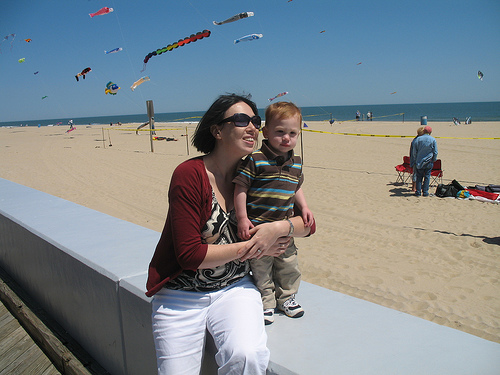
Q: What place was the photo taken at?
A: It was taken at the beach.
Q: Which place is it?
A: It is a beach.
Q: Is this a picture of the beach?
A: Yes, it is showing the beach.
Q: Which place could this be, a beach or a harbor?
A: It is a beach.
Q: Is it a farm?
A: No, it is a beach.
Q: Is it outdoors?
A: Yes, it is outdoors.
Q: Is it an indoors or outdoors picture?
A: It is outdoors.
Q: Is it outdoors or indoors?
A: It is outdoors.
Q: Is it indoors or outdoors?
A: It is outdoors.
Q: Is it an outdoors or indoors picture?
A: It is outdoors.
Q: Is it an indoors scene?
A: No, it is outdoors.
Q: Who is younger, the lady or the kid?
A: The kid is younger than the lady.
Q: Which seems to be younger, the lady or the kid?
A: The kid is younger than the lady.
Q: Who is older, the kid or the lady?
A: The lady is older than the kid.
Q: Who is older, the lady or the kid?
A: The lady is older than the kid.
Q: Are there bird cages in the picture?
A: No, there are no bird cages.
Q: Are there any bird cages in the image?
A: No, there are no bird cages.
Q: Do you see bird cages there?
A: No, there are no bird cages.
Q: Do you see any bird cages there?
A: No, there are no bird cages.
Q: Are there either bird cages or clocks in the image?
A: No, there are no bird cages or clocks.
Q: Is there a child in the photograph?
A: Yes, there is a child.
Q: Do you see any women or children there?
A: Yes, there is a child.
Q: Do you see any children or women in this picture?
A: Yes, there is a child.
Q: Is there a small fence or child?
A: Yes, there is a small child.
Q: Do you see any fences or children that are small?
A: Yes, the child is small.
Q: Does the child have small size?
A: Yes, the child is small.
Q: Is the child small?
A: Yes, the child is small.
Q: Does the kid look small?
A: Yes, the kid is small.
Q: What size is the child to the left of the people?
A: The child is small.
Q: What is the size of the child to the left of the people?
A: The child is small.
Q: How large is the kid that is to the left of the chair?
A: The child is small.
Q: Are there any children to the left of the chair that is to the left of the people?
A: Yes, there is a child to the left of the chair.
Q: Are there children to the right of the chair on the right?
A: No, the child is to the left of the chair.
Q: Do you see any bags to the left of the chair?
A: No, there is a child to the left of the chair.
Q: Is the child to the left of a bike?
A: No, the child is to the left of the chair.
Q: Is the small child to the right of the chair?
A: No, the kid is to the left of the chair.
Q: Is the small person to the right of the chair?
A: No, the kid is to the left of the chair.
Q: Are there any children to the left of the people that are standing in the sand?
A: Yes, there is a child to the left of the people.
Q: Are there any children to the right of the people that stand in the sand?
A: No, the child is to the left of the people.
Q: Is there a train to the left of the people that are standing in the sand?
A: No, there is a child to the left of the people.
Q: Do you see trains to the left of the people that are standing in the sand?
A: No, there is a child to the left of the people.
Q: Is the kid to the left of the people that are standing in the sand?
A: Yes, the kid is to the left of the people.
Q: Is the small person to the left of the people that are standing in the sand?
A: Yes, the kid is to the left of the people.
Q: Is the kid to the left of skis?
A: No, the kid is to the left of the people.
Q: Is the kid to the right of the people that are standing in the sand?
A: No, the kid is to the left of the people.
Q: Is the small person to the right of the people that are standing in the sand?
A: No, the kid is to the left of the people.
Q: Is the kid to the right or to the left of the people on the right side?
A: The kid is to the left of the people.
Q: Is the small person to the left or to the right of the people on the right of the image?
A: The kid is to the left of the people.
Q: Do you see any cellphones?
A: No, there are no cellphones.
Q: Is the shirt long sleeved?
A: Yes, the shirt is long sleeved.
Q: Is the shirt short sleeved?
A: No, the shirt is long sleeved.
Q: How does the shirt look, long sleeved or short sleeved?
A: The shirt is long sleeved.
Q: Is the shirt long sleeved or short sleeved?
A: The shirt is long sleeved.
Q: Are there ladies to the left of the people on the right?
A: Yes, there is a lady to the left of the people.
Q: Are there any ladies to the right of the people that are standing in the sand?
A: No, the lady is to the left of the people.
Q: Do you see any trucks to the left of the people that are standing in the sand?
A: No, there is a lady to the left of the people.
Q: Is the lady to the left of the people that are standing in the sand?
A: Yes, the lady is to the left of the people.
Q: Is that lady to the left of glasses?
A: No, the lady is to the left of the people.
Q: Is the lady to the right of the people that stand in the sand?
A: No, the lady is to the left of the people.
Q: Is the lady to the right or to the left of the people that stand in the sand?
A: The lady is to the left of the people.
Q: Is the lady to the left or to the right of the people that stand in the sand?
A: The lady is to the left of the people.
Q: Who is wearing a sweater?
A: The lady is wearing a sweater.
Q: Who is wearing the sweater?
A: The lady is wearing a sweater.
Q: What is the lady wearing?
A: The lady is wearing a sweater.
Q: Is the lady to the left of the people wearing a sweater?
A: Yes, the lady is wearing a sweater.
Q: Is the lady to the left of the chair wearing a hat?
A: No, the lady is wearing a sweater.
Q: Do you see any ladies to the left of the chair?
A: Yes, there is a lady to the left of the chair.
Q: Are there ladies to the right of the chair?
A: No, the lady is to the left of the chair.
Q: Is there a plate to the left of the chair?
A: No, there is a lady to the left of the chair.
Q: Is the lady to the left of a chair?
A: Yes, the lady is to the left of a chair.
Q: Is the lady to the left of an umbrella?
A: No, the lady is to the left of a chair.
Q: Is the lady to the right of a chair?
A: No, the lady is to the left of a chair.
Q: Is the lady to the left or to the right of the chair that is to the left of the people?
A: The lady is to the left of the chair.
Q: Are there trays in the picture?
A: No, there are no trays.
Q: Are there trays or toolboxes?
A: No, there are no trays or toolboxes.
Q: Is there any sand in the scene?
A: Yes, there is sand.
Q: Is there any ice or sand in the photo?
A: Yes, there is sand.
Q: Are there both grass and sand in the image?
A: No, there is sand but no grass.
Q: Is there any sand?
A: Yes, there is sand.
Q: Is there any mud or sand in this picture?
A: Yes, there is sand.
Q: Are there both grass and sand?
A: No, there is sand but no grass.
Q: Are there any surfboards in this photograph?
A: No, there are no surfboards.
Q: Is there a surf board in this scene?
A: No, there are no surfboards.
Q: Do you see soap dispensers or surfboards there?
A: No, there are no surfboards or soap dispensers.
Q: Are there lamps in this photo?
A: No, there are no lamps.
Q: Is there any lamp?
A: No, there are no lamps.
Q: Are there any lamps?
A: No, there are no lamps.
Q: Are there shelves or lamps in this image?
A: No, there are no lamps or shelves.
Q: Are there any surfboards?
A: No, there are no surfboards.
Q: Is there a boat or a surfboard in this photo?
A: No, there are no surfboards or boats.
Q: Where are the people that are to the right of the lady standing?
A: The people are standing in the sand.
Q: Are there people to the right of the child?
A: Yes, there are people to the right of the child.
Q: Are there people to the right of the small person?
A: Yes, there are people to the right of the child.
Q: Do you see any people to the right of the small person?
A: Yes, there are people to the right of the child.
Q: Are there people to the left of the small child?
A: No, the people are to the right of the child.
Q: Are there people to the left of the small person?
A: No, the people are to the right of the child.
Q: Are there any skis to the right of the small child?
A: No, there are people to the right of the kid.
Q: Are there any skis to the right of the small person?
A: No, there are people to the right of the kid.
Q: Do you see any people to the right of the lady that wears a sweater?
A: Yes, there are people to the right of the lady.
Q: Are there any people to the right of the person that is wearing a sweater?
A: Yes, there are people to the right of the lady.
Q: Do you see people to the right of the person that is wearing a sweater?
A: Yes, there are people to the right of the lady.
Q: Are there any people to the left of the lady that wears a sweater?
A: No, the people are to the right of the lady.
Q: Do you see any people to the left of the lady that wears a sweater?
A: No, the people are to the right of the lady.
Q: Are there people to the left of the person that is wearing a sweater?
A: No, the people are to the right of the lady.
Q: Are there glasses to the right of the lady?
A: No, there are people to the right of the lady.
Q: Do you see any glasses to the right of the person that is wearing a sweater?
A: No, there are people to the right of the lady.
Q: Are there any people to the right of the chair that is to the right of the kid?
A: Yes, there are people to the right of the chair.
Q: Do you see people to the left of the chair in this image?
A: No, the people are to the right of the chair.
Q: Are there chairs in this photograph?
A: Yes, there is a chair.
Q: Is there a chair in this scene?
A: Yes, there is a chair.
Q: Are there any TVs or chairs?
A: Yes, there is a chair.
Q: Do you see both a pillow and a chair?
A: No, there is a chair but no pillows.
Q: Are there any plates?
A: No, there are no plates.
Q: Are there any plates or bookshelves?
A: No, there are no plates or bookshelves.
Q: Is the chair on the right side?
A: Yes, the chair is on the right of the image.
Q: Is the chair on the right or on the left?
A: The chair is on the right of the image.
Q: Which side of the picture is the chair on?
A: The chair is on the right of the image.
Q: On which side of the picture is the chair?
A: The chair is on the right of the image.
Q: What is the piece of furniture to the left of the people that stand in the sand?
A: The piece of furniture is a chair.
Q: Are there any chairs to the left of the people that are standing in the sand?
A: Yes, there is a chair to the left of the people.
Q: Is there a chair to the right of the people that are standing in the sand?
A: No, the chair is to the left of the people.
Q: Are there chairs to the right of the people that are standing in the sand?
A: No, the chair is to the left of the people.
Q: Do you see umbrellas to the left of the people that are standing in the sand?
A: No, there is a chair to the left of the people.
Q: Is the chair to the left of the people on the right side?
A: Yes, the chair is to the left of the people.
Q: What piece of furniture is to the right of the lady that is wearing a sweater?
A: The piece of furniture is a chair.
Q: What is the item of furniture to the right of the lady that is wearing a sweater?
A: The piece of furniture is a chair.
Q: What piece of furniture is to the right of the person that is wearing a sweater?
A: The piece of furniture is a chair.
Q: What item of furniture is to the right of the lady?
A: The piece of furniture is a chair.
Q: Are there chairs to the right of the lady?
A: Yes, there is a chair to the right of the lady.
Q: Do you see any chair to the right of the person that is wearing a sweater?
A: Yes, there is a chair to the right of the lady.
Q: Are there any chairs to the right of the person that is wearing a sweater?
A: Yes, there is a chair to the right of the lady.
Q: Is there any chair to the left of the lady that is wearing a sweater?
A: No, the chair is to the right of the lady.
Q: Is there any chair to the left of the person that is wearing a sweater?
A: No, the chair is to the right of the lady.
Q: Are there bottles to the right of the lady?
A: No, there is a chair to the right of the lady.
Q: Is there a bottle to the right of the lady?
A: No, there is a chair to the right of the lady.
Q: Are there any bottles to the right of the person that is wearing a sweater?
A: No, there is a chair to the right of the lady.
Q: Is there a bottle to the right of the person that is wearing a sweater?
A: No, there is a chair to the right of the lady.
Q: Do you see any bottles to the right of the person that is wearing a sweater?
A: No, there is a chair to the right of the lady.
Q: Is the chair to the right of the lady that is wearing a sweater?
A: Yes, the chair is to the right of the lady.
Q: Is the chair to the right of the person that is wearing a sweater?
A: Yes, the chair is to the right of the lady.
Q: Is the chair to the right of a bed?
A: No, the chair is to the right of the lady.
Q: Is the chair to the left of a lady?
A: No, the chair is to the right of a lady.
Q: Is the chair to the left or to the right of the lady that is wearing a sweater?
A: The chair is to the right of the lady.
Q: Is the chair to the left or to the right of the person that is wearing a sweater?
A: The chair is to the right of the lady.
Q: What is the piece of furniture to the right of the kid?
A: The piece of furniture is a chair.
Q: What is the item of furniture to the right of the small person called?
A: The piece of furniture is a chair.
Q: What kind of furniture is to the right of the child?
A: The piece of furniture is a chair.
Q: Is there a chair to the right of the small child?
A: Yes, there is a chair to the right of the child.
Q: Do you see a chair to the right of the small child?
A: Yes, there is a chair to the right of the child.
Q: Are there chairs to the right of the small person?
A: Yes, there is a chair to the right of the child.